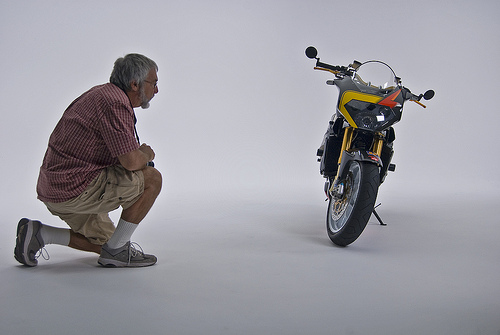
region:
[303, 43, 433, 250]
yellow and red motorcycle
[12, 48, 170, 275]
man kneeling next to motorcycle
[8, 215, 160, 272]
man wearing grey tennis shoes with white bottoms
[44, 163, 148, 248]
man wearing khaki shorts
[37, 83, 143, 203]
man wearing red plaid shirt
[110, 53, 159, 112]
man with salt and pepper beard and mustache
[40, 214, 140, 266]
man wearing long white socks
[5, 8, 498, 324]
picture taken in all white room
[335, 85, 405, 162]
yellow stripe and red firebolt design on bike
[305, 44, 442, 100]
two front rear view mirrors on motorcycle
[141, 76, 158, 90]
glasses on a man's face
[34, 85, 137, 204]
a red checkered shirt on a man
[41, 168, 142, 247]
tan shorts on a man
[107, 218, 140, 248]
a white sock on a man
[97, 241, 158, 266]
a gray shoe on a man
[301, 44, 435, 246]
a yellow and black motorcycle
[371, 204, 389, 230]
the kickstand of a motorcycle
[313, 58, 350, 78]
the handlebar of a motorcycle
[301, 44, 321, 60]
the side mirror on a motorcycle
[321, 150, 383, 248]
the front wheel of a motorcycle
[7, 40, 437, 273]
A man looking at a motorcycle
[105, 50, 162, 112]
A man has gray hair and a beard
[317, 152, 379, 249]
A black rubber tire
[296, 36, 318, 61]
A side mirror is round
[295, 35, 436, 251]
A motorcycle is yellow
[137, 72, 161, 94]
A pair of glasses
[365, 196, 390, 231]
The kickstand is down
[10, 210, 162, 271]
A pair of sneakers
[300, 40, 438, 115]
Handlebars of a motorbike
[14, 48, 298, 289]
a man kneeling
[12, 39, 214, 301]
a man kneeling on the ground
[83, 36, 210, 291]
a man with gray hair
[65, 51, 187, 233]
a man wearing a button down shirt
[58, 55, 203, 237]
a man wearing shorts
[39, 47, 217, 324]
a man wearing socks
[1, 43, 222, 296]
a man wearing shoes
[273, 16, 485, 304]
a yellow motorcyle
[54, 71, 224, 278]
a man is kneeling down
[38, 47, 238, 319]
the man is looking at a motorbike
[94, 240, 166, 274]
shoes are gray in color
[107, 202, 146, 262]
socks are white incolor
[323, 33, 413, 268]
the motorbike is at a stand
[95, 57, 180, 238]
th man is wearing spectacles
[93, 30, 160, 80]
the hair i gray in color